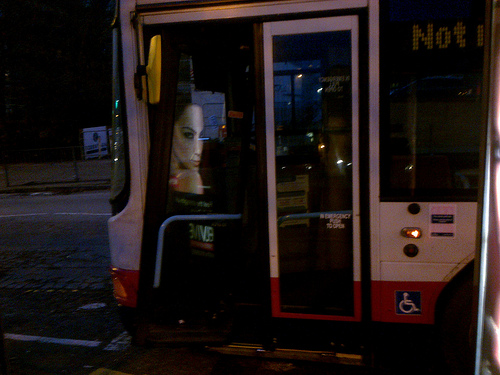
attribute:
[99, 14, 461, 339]
bus — sitting, red, traveling, empty, transit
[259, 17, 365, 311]
door — emergency, closed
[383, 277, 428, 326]
sign — handicap, blue, handicapped symbol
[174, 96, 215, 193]
ad — faded, white, jennifer lopez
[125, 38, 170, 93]
mirror — yellow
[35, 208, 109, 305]
street — asphalt, dim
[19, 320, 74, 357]
line — white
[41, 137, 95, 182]
gate — gray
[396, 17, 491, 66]
text — yellow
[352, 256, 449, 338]
stripe — red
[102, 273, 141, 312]
reflector — orange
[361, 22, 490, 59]
sign — neon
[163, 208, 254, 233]
rod — blue